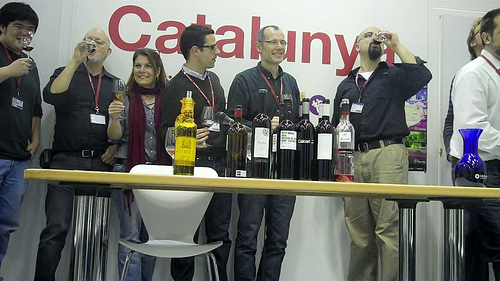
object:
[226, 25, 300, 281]
man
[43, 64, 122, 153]
black shirt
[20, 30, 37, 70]
wine glass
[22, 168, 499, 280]
table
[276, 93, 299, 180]
wine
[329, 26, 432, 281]
man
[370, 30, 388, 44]
glass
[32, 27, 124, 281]
man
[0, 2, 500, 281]
people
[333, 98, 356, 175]
wine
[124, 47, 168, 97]
brown hair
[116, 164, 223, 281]
chair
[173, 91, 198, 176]
bottle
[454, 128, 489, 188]
vase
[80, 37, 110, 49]
glasses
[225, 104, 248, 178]
glasss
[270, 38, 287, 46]
glass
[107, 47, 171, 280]
woman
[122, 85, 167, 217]
scarf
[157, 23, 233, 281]
man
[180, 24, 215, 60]
hair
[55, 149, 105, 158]
belt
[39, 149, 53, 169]
phone case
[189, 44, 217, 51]
glasses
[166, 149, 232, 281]
jeans